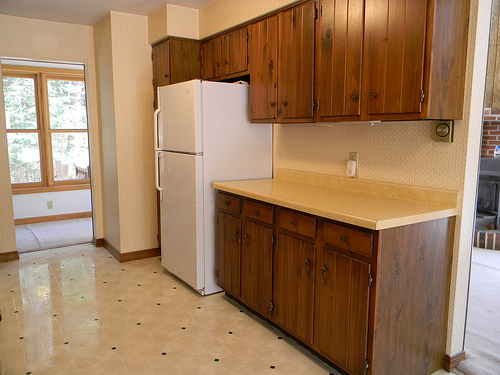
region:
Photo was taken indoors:
[16, 6, 494, 356]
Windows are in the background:
[5, 75, 90, 182]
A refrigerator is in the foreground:
[146, 72, 283, 299]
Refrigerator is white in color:
[144, 71, 290, 301]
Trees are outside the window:
[3, 79, 88, 179]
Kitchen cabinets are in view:
[242, 0, 480, 122]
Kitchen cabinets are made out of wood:
[242, 4, 476, 127]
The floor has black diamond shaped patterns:
[5, 263, 273, 373]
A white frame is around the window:
[1, 62, 92, 195]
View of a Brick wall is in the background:
[468, 101, 499, 248]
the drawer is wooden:
[337, 294, 346, 320]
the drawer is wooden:
[344, 296, 355, 325]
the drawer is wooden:
[333, 308, 343, 330]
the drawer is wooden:
[342, 307, 353, 339]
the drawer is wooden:
[338, 290, 347, 312]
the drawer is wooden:
[336, 308, 348, 336]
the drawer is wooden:
[322, 299, 337, 327]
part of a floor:
[163, 324, 196, 357]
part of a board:
[324, 312, 359, 349]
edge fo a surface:
[360, 212, 405, 233]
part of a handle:
[139, 130, 165, 199]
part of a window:
[3, 149, 28, 178]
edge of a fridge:
[194, 250, 213, 285]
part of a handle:
[317, 249, 347, 296]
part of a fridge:
[163, 212, 195, 255]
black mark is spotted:
[210, 346, 219, 371]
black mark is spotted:
[214, 355, 223, 365]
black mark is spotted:
[214, 357, 222, 359]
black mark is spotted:
[218, 360, 222, 365]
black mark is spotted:
[217, 348, 219, 371]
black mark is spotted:
[209, 351, 224, 372]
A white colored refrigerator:
[152, 80, 272, 296]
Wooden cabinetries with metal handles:
[214, 192, 390, 374]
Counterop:
[212, 166, 460, 226]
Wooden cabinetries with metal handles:
[148, 0, 463, 121]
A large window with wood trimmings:
[0, 64, 91, 192]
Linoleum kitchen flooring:
[3, 262, 156, 373]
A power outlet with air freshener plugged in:
[345, 151, 361, 178]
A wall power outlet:
[46, 198, 54, 210]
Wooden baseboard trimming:
[14, 209, 94, 224]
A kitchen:
[1, 1, 477, 374]